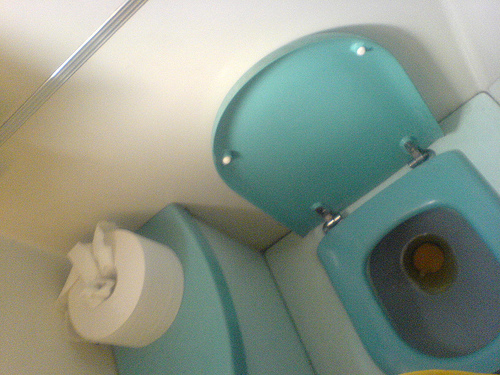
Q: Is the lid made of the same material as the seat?
A: Yes, both the lid and the seat are made of plastic.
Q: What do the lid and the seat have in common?
A: The material, both the lid and the seat are plastic.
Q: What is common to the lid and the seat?
A: The material, both the lid and the seat are plastic.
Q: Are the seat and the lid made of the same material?
A: Yes, both the seat and the lid are made of plastic.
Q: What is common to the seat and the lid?
A: The material, both the seat and the lid are plastic.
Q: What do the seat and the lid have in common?
A: The material, both the seat and the lid are plastic.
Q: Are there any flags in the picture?
A: No, there are no flags.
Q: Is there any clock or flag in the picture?
A: No, there are no flags or clocks.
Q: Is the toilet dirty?
A: Yes, the toilet is dirty.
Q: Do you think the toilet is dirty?
A: Yes, the toilet is dirty.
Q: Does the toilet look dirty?
A: Yes, the toilet is dirty.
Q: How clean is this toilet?
A: The toilet is dirty.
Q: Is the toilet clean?
A: No, the toilet is dirty.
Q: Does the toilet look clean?
A: No, the toilet is dirty.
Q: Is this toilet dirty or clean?
A: The toilet is dirty.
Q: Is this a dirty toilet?
A: Yes, this is a dirty toilet.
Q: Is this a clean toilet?
A: No, this is a dirty toilet.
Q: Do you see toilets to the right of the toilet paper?
A: Yes, there is a toilet to the right of the toilet paper.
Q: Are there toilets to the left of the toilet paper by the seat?
A: No, the toilet is to the right of the toilet paper.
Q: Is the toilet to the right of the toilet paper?
A: Yes, the toilet is to the right of the toilet paper.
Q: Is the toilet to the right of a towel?
A: No, the toilet is to the right of the toilet paper.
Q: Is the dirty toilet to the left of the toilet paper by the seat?
A: No, the toilet is to the right of the toilet paper.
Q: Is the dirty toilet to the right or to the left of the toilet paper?
A: The toilet is to the right of the toilet paper.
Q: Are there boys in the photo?
A: No, there are no boys.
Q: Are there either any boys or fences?
A: No, there are no boys or fences.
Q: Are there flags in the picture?
A: No, there are no flags.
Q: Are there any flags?
A: No, there are no flags.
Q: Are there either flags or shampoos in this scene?
A: No, there are no flags or shampoos.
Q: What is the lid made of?
A: The lid is made of plastic.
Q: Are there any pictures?
A: No, there are no pictures.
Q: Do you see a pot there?
A: No, there are no pots.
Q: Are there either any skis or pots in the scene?
A: No, there are no pots or skis.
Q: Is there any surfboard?
A: No, there are no surfboards.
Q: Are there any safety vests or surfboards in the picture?
A: No, there are no surfboards or safety vests.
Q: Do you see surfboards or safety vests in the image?
A: No, there are no surfboards or safety vests.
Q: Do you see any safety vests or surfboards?
A: No, there are no surfboards or safety vests.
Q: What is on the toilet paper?
A: The paper is on the toilet paper.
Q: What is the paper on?
A: The paper is on the toilet paper.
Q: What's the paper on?
A: The paper is on the toilet paper.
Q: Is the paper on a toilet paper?
A: Yes, the paper is on a toilet paper.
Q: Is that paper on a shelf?
A: No, the paper is on a toilet paper.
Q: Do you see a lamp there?
A: No, there are no lamps.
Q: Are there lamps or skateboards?
A: No, there are no lamps or skateboards.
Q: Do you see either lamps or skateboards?
A: No, there are no lamps or skateboards.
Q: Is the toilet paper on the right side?
A: No, the toilet paper is on the left of the image.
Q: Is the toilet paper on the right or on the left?
A: The toilet paper is on the left of the image.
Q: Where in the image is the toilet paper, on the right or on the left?
A: The toilet paper is on the left of the image.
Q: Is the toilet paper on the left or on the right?
A: The toilet paper is on the left of the image.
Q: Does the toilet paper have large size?
A: Yes, the toilet paper is large.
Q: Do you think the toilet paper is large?
A: Yes, the toilet paper is large.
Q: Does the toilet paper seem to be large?
A: Yes, the toilet paper is large.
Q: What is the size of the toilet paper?
A: The toilet paper is large.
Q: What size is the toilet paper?
A: The toilet paper is large.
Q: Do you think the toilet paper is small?
A: No, the toilet paper is large.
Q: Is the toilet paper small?
A: No, the toilet paper is large.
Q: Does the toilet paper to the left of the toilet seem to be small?
A: No, the toilet paper is large.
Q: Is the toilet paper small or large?
A: The toilet paper is large.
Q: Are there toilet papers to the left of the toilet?
A: Yes, there is a toilet paper to the left of the toilet.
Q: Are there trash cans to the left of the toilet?
A: No, there is a toilet paper to the left of the toilet.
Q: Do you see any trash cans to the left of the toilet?
A: No, there is a toilet paper to the left of the toilet.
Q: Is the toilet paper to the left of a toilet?
A: Yes, the toilet paper is to the left of a toilet.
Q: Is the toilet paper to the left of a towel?
A: No, the toilet paper is to the left of a toilet.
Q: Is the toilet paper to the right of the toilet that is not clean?
A: No, the toilet paper is to the left of the toilet.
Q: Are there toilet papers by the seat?
A: Yes, there is a toilet paper by the seat.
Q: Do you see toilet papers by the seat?
A: Yes, there is a toilet paper by the seat.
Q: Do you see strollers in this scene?
A: No, there are no strollers.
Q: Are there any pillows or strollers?
A: No, there are no strollers or pillows.